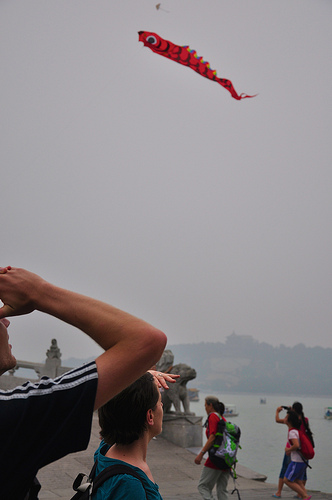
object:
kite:
[135, 29, 259, 101]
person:
[69, 363, 181, 499]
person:
[0, 255, 168, 498]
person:
[192, 392, 233, 498]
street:
[0, 378, 332, 500]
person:
[214, 398, 227, 418]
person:
[282, 408, 314, 500]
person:
[270, 397, 316, 500]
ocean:
[166, 391, 332, 497]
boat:
[223, 404, 239, 418]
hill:
[60, 329, 330, 397]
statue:
[146, 346, 202, 446]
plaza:
[1, 402, 329, 499]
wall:
[0, 334, 205, 447]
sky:
[0, 0, 331, 328]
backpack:
[210, 416, 241, 473]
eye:
[146, 36, 156, 47]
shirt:
[89, 435, 166, 499]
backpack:
[67, 453, 153, 500]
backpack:
[297, 427, 315, 462]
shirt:
[201, 408, 232, 472]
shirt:
[0, 360, 98, 499]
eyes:
[0, 307, 6, 324]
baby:
[301, 420, 315, 447]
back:
[301, 417, 311, 438]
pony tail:
[299, 411, 314, 438]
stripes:
[0, 371, 100, 400]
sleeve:
[0, 352, 98, 470]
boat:
[188, 385, 201, 403]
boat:
[258, 398, 266, 406]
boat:
[321, 405, 332, 422]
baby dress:
[212, 417, 243, 467]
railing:
[1, 338, 89, 388]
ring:
[156, 372, 163, 379]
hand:
[145, 368, 177, 393]